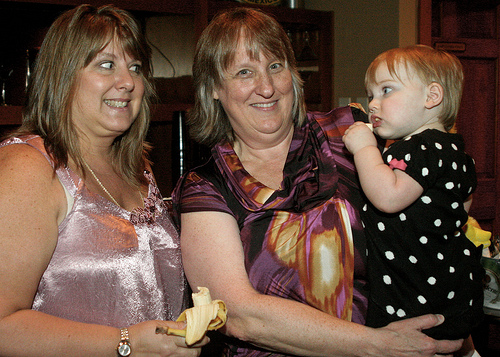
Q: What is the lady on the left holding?
A: A banana.